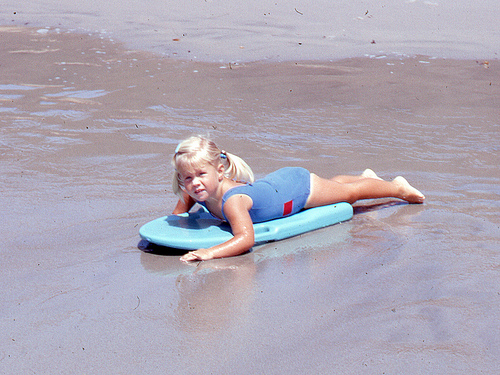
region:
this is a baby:
[155, 127, 426, 226]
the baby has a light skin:
[206, 174, 216, 187]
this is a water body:
[307, 262, 419, 342]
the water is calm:
[321, 236, 366, 298]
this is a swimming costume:
[264, 178, 291, 200]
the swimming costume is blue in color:
[256, 180, 273, 209]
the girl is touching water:
[182, 246, 224, 269]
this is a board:
[154, 225, 200, 245]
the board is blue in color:
[159, 228, 191, 250]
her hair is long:
[218, 146, 246, 176]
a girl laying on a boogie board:
[100, 139, 443, 274]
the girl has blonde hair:
[164, 140, 264, 202]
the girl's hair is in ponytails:
[162, 140, 243, 194]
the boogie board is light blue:
[132, 205, 361, 265]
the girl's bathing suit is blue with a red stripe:
[209, 155, 330, 230]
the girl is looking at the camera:
[162, 139, 244, 236]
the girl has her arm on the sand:
[173, 238, 288, 278]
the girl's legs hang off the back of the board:
[277, 157, 437, 232]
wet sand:
[252, 265, 486, 367]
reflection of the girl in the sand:
[157, 248, 262, 337]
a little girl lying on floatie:
[107, 122, 425, 268]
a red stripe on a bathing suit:
[283, 198, 297, 215]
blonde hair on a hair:
[186, 137, 203, 152]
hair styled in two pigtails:
[166, 140, 254, 166]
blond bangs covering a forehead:
[176, 157, 203, 167]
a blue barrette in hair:
[219, 152, 228, 159]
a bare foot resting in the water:
[399, 174, 422, 204]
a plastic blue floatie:
[160, 220, 205, 245]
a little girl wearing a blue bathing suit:
[157, 132, 419, 264]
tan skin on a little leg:
[351, 177, 393, 198]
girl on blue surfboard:
[131, 133, 430, 273]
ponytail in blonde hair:
[215, 145, 253, 187]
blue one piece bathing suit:
[214, 162, 319, 227]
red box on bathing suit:
[275, 198, 301, 221]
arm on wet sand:
[169, 243, 241, 272]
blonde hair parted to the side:
[182, 133, 215, 164]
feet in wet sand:
[361, 163, 434, 208]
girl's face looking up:
[181, 163, 213, 202]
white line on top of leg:
[299, 170, 319, 212]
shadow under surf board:
[126, 239, 181, 262]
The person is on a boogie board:
[130, 128, 424, 274]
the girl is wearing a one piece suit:
[123, 131, 422, 266]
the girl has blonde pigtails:
[166, 135, 255, 205]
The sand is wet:
[1, 3, 498, 369]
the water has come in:
[2, 22, 498, 374]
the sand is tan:
[3, 3, 495, 60]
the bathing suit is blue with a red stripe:
[200, 165, 317, 229]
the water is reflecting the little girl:
[136, 132, 427, 340]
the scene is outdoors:
[1, 1, 498, 373]